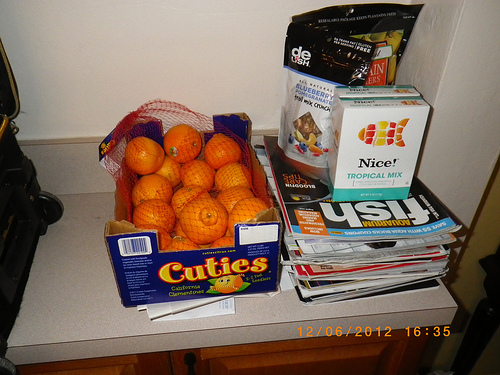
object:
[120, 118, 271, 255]
oranges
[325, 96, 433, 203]
box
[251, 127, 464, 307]
magazines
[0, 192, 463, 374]
counter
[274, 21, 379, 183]
nuts